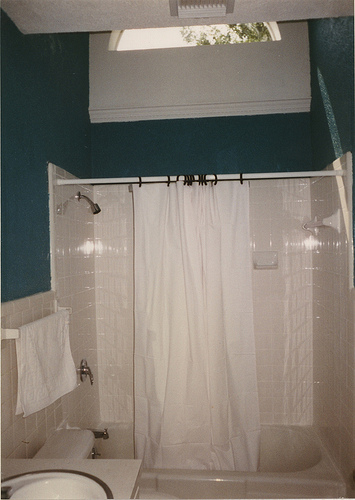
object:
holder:
[251, 249, 278, 271]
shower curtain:
[133, 181, 263, 474]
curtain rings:
[137, 171, 245, 186]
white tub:
[87, 400, 350, 497]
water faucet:
[96, 428, 111, 442]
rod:
[53, 168, 347, 186]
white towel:
[14, 310, 79, 415]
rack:
[3, 324, 20, 338]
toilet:
[14, 400, 139, 482]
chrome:
[75, 187, 103, 219]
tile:
[283, 184, 312, 421]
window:
[113, 20, 284, 51]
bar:
[264, 185, 350, 285]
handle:
[72, 357, 100, 386]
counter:
[3, 448, 151, 499]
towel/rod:
[12, 305, 79, 420]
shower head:
[57, 192, 122, 224]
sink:
[1, 466, 113, 500]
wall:
[6, 146, 31, 271]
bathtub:
[83, 410, 348, 498]